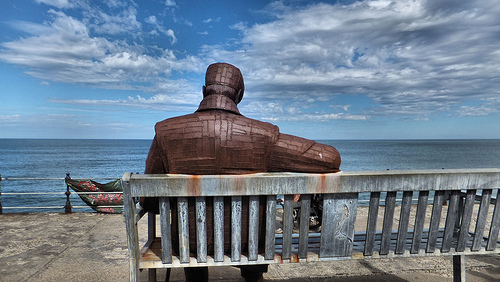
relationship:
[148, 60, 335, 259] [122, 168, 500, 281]
wooden figure sitting on bench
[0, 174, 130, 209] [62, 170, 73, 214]
fence with post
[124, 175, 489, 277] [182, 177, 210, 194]
bench has rust patch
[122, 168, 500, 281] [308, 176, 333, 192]
bench has rust patch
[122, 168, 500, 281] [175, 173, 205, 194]
bench has rust patch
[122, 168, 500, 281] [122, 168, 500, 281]
bench has bench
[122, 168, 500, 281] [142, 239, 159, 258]
bench has patch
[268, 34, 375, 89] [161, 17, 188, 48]
white clouds in blue sky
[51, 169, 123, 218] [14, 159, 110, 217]
cloth on railing